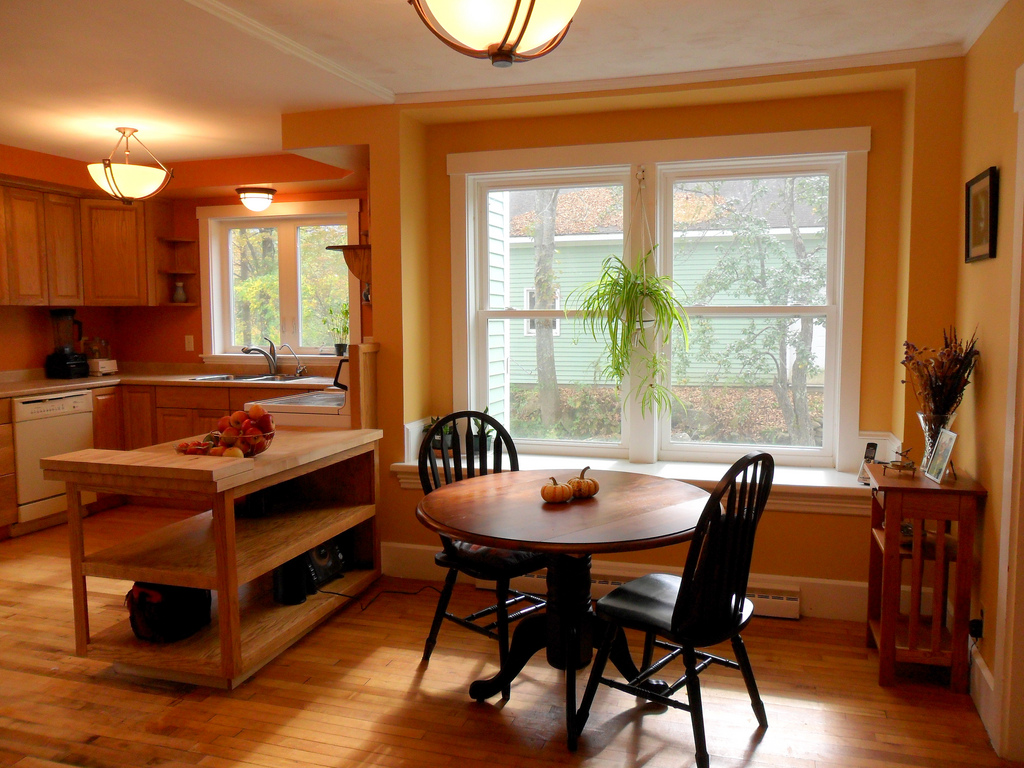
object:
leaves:
[564, 243, 692, 421]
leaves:
[633, 323, 669, 421]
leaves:
[722, 196, 766, 244]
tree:
[668, 173, 830, 448]